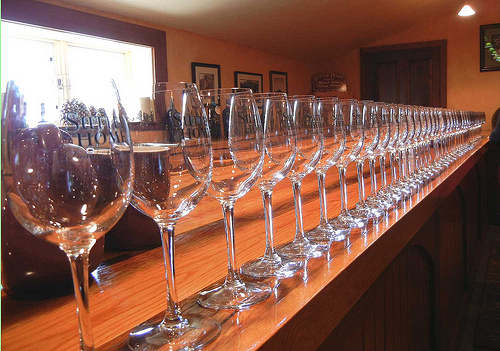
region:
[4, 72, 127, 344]
a clear stemmed wine glass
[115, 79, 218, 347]
a clear stemmed wine glass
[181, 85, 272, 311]
a clear stemmed wine glass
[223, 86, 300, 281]
a clear stemmed wine glass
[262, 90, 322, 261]
a clear stemmed wine glass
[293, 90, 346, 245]
a clear stemmed wine glass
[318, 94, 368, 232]
a clear stemmed wine glass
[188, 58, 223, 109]
a framed print on wall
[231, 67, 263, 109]
a framed print on wall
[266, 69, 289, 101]
a framed print on wall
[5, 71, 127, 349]
Tall wine glass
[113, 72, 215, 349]
Clear wine glass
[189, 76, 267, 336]
Clear wine glass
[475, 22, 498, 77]
Picture in frame on the wall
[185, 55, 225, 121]
Picture in frame on the wall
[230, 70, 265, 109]
Picture in frame on the wall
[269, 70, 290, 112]
Picture in frame on the wall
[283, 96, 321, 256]
Clear wine glass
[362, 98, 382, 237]
Clear wine glass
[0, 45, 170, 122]
Long bright window in the background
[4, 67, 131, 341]
clear empty wine glass on wooden counter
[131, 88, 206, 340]
clear empty wine glass on wooden counter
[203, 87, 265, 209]
clear empty wine glass on wooden counter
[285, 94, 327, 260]
clear empty wine glass on wooden counter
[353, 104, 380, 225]
clear empty wine glasses on wooden counter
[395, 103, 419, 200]
clear empty wine glass on wooden counter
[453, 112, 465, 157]
clear empty wine glass on wooden counter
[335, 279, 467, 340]
wooden counter at bar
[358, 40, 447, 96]
brown wooden door in bar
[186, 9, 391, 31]
white ceiling in bar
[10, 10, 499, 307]
a table full of glasses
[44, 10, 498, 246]
a bar full of whine glasses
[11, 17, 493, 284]
wine glasses in a row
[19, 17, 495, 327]
wine glasses in a straight row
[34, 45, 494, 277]
wine glasses lined up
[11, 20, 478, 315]
empty wine glasses lined up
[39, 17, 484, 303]
empty wine glasses in a row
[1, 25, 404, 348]
clean wine glasses in a row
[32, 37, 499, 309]
clean clear glasses on bar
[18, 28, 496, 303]
clean clear glasses in row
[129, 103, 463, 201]
row of wine glasses on bar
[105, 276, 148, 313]
wood grain in bar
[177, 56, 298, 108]
three pictures on wall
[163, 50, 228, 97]
black frame on picture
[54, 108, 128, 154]
words on side of glass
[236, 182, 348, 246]
stems of wine glasses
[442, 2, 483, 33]
light suspended from ceiling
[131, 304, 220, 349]
base of wine glass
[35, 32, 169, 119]
sunlight shining through window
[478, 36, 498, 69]
reflection on picture glass